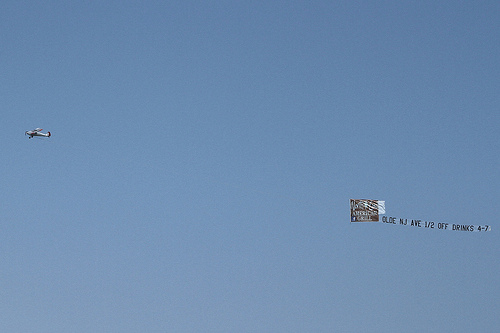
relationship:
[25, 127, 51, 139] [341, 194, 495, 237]
airplane dragging sign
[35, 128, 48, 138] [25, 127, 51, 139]
wing of airplane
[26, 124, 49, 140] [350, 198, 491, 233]
airplane pulling advertisement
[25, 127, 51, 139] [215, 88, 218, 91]
airplane in air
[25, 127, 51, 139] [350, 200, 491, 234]
airplane pulling banner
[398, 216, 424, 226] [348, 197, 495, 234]
nj ave on sign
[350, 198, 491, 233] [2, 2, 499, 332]
advertisement in sky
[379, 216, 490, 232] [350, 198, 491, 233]
words on advertisement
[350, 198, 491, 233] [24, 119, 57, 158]
advertisement pulled by airplane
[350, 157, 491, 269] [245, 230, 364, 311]
advertisement in air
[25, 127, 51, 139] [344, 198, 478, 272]
airplane pulling banner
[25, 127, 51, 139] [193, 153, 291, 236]
airplane in sky